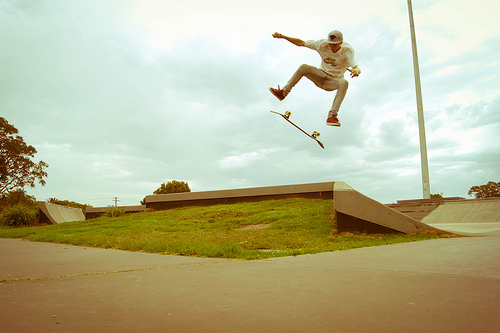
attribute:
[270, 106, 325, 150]
skateboard — mid air, upside down, in air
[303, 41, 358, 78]
shirt — cotton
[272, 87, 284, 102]
sneaker — red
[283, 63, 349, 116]
jeans — tan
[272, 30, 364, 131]
man — skateboarder, skateboarding, kick flipping, mid air, doing tricks, doing trick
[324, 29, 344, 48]
hat — light colored, silver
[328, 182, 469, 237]
ramp — concrete, tan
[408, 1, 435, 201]
pole — white, tall, post, metal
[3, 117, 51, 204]
tree — green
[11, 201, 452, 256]
grass — green